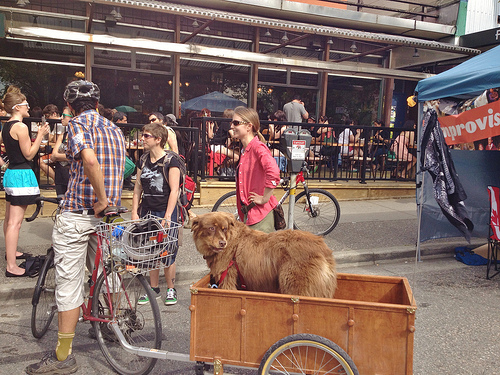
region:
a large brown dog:
[195, 208, 340, 306]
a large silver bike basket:
[92, 216, 184, 269]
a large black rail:
[262, 120, 419, 185]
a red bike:
[23, 232, 168, 374]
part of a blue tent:
[399, 48, 499, 274]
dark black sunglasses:
[232, 117, 244, 131]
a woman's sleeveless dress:
[2, 118, 45, 208]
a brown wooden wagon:
[181, 269, 416, 374]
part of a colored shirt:
[67, 103, 131, 208]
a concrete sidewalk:
[165, 194, 486, 273]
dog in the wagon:
[184, 212, 349, 291]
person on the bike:
[68, 89, 118, 341]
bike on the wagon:
[252, 324, 374, 374]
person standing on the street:
[224, 105, 301, 230]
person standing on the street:
[136, 125, 196, 297]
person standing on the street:
[0, 97, 53, 281]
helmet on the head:
[66, 79, 97, 103]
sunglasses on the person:
[231, 120, 246, 129]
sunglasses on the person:
[141, 130, 159, 141]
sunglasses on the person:
[13, 103, 30, 109]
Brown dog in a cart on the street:
[187, 210, 332, 295]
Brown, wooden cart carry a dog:
[186, 271, 416, 372]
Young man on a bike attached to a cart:
[22, 78, 125, 373]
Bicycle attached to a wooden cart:
[25, 197, 183, 372]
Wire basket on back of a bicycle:
[92, 210, 182, 272]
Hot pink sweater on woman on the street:
[232, 135, 282, 221]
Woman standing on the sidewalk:
[0, 86, 52, 276]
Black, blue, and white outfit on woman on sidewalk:
[0, 117, 40, 204]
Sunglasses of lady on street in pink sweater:
[226, 116, 246, 127]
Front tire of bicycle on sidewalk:
[286, 185, 341, 237]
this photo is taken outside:
[17, 14, 482, 321]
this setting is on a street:
[19, 53, 494, 350]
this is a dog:
[177, 200, 377, 306]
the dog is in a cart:
[139, 191, 468, 373]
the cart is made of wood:
[180, 286, 441, 358]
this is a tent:
[392, 34, 499, 156]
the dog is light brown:
[188, 206, 425, 348]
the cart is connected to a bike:
[37, 221, 317, 370]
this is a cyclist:
[28, 57, 143, 341]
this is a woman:
[212, 105, 287, 210]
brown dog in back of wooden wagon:
[182, 198, 342, 300]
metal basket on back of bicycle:
[83, 208, 188, 282]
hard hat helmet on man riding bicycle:
[60, 75, 102, 107]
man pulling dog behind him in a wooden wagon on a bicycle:
[15, 75, 430, 373]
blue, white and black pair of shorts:
[0, 158, 48, 212]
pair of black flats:
[2, 243, 34, 282]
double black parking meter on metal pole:
[275, 122, 315, 227]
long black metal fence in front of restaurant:
[0, 106, 417, 186]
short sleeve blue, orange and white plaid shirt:
[55, 108, 129, 218]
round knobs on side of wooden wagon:
[182, 297, 417, 337]